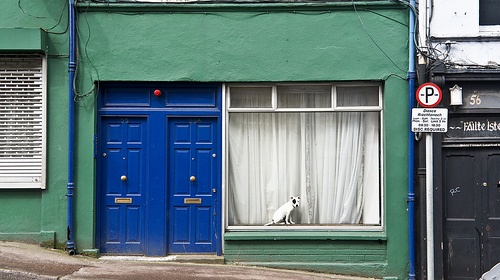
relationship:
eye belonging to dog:
[291, 197, 297, 204] [261, 194, 301, 227]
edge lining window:
[377, 84, 384, 230] [223, 83, 382, 230]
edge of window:
[340, 227, 373, 245] [244, 105, 376, 232]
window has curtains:
[220, 117, 381, 234] [241, 128, 361, 215]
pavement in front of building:
[90, 247, 295, 273] [44, 20, 405, 271]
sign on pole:
[403, 64, 447, 130] [405, 72, 445, 267]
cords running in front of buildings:
[410, 39, 448, 83] [20, 0, 467, 275]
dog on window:
[260, 186, 308, 231] [225, 110, 375, 222]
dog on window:
[260, 186, 308, 231] [219, 93, 381, 229]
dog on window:
[260, 186, 308, 231] [212, 104, 389, 239]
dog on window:
[260, 186, 308, 231] [219, 113, 388, 228]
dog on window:
[260, 186, 308, 231] [227, 78, 389, 247]